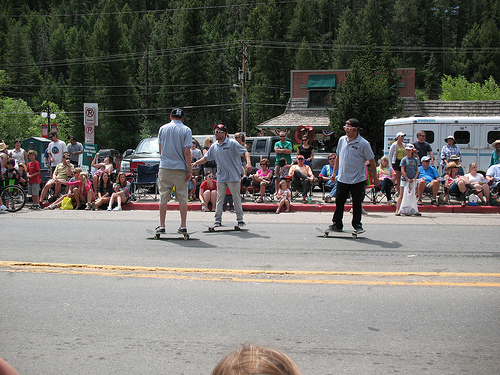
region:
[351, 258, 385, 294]
part f a line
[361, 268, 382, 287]
part f a line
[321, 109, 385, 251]
this is a man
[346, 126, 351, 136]
the man is light skinned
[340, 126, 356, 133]
this is a spectacle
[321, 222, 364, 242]
this is a skateboard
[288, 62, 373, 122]
this is a building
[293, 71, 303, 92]
this is the wall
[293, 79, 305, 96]
the wall is brown in color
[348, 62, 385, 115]
this is a tree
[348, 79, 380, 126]
the leaves are green in color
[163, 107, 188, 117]
this is a cap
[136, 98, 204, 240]
This is a person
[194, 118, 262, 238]
This is a person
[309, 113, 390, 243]
This is a person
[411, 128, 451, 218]
This is a person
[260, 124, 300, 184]
This is a person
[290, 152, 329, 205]
This is a person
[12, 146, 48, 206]
This is a person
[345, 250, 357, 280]
part of a linme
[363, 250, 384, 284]
part f a line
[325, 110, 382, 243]
This is a person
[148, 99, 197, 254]
This is a person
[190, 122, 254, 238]
This is a person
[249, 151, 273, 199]
This is a person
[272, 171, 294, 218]
This is a person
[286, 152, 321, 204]
This is a person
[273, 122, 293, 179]
This is a person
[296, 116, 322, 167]
This is a person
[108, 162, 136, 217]
This is a person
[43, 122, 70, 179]
This is a person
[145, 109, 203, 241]
person skating in middle of road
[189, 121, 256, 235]
person skating in middle of road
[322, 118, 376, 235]
person skating in middle of road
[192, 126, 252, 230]
skater talking to other skater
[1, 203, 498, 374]
a paved city street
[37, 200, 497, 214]
a red painted curb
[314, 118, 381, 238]
a skateboarder in street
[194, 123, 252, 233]
a skateboarder in street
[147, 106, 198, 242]
a skateboarder in street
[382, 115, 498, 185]
a white commercial truck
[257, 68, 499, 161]
a brown building in distance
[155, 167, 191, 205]
a pair of tan shorts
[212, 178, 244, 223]
a pair of white pants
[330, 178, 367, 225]
a pair of black pants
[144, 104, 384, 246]
Three men skateboarding road.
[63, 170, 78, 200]
a person is sitting down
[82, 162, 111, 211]
a person is sitting down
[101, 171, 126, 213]
a person is sitting down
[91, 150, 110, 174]
a person is sitting down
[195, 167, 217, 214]
a person is sitting down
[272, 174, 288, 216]
a person is sitting down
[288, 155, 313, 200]
a person is sitting down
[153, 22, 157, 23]
A green leaf on a plant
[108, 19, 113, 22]
A green leaf on a plant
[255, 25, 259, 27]
A green leaf on a plant